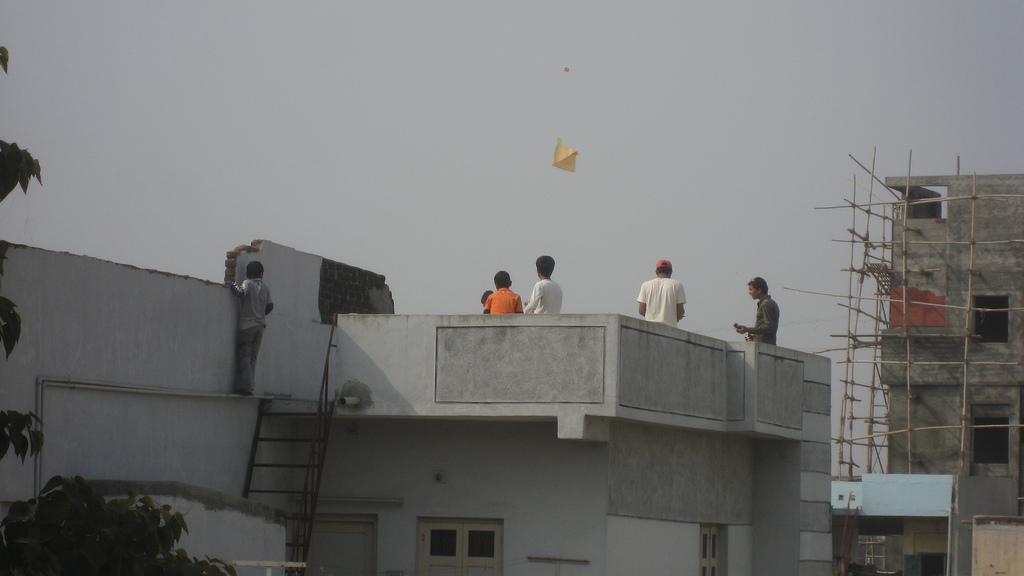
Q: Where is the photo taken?
A: On the street.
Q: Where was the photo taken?
A: Rooftop.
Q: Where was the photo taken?
A: Top of building.